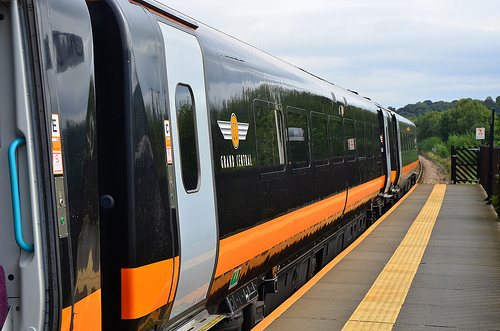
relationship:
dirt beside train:
[420, 152, 450, 184] [1, 0, 420, 329]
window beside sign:
[174, 81, 204, 194] [163, 121, 174, 167]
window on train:
[253, 103, 284, 171] [1, 0, 420, 329]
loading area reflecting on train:
[247, 183, 500, 329] [1, 0, 420, 329]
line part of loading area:
[334, 183, 451, 331] [247, 183, 500, 329]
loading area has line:
[247, 183, 500, 329] [249, 180, 419, 331]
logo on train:
[216, 113, 250, 151] [1, 0, 420, 329]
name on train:
[220, 155, 252, 169] [1, 0, 420, 329]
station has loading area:
[1, 2, 500, 331] [247, 183, 500, 329]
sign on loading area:
[476, 127, 486, 141] [247, 183, 500, 329]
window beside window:
[253, 103, 284, 171] [285, 111, 310, 168]